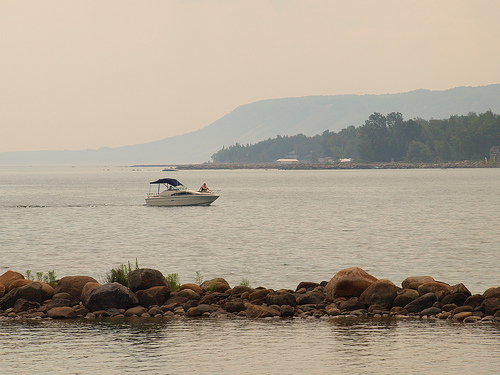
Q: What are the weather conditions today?
A: It is overcast.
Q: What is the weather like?
A: It is overcast.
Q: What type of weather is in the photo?
A: It is overcast.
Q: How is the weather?
A: It is overcast.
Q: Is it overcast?
A: Yes, it is overcast.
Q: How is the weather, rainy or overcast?
A: It is overcast.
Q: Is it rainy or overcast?
A: It is overcast.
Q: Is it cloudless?
A: No, it is overcast.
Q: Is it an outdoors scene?
A: Yes, it is outdoors.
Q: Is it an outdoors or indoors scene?
A: It is outdoors.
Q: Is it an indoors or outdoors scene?
A: It is outdoors.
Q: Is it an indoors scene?
A: No, it is outdoors.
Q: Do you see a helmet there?
A: No, there are no helmets.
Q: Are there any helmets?
A: No, there are no helmets.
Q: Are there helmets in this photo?
A: No, there are no helmets.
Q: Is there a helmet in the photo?
A: No, there are no helmets.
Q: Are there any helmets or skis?
A: No, there are no helmets or skis.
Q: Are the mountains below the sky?
A: Yes, the mountains are below the sky.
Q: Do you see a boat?
A: Yes, there is a boat.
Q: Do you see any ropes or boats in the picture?
A: Yes, there is a boat.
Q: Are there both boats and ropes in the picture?
A: No, there is a boat but no ropes.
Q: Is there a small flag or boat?
A: Yes, there is a small boat.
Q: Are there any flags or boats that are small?
A: Yes, the boat is small.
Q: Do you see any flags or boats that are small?
A: Yes, the boat is small.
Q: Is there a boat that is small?
A: Yes, there is a small boat.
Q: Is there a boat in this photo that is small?
A: Yes, there is a boat that is small.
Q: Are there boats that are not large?
A: Yes, there is a small boat.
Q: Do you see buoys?
A: No, there are no buoys.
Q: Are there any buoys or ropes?
A: No, there are no buoys or ropes.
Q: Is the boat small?
A: Yes, the boat is small.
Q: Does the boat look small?
A: Yes, the boat is small.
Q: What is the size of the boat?
A: The boat is small.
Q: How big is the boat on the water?
A: The boat is small.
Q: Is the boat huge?
A: No, the boat is small.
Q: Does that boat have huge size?
A: No, the boat is small.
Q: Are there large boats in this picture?
A: No, there is a boat but it is small.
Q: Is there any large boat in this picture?
A: No, there is a boat but it is small.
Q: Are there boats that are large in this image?
A: No, there is a boat but it is small.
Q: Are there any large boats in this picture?
A: No, there is a boat but it is small.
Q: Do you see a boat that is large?
A: No, there is a boat but it is small.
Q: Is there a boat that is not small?
A: No, there is a boat but it is small.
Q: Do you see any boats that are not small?
A: No, there is a boat but it is small.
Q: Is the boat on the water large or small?
A: The boat is small.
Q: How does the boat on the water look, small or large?
A: The boat is small.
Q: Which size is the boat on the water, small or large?
A: The boat is small.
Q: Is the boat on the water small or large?
A: The boat is small.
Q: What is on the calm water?
A: The boat is on the water.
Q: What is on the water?
A: The boat is on the water.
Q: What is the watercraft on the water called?
A: The watercraft is a boat.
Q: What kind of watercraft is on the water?
A: The watercraft is a boat.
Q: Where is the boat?
A: The boat is on the water.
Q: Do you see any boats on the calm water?
A: Yes, there is a boat on the water.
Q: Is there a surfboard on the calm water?
A: No, there is a boat on the water.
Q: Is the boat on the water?
A: Yes, the boat is on the water.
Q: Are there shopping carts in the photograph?
A: No, there are no shopping carts.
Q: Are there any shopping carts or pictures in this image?
A: No, there are no shopping carts or pictures.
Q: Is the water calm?
A: Yes, the water is calm.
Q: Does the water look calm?
A: Yes, the water is calm.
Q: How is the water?
A: The water is calm.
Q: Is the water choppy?
A: No, the water is calm.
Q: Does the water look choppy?
A: No, the water is calm.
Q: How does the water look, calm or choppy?
A: The water is calm.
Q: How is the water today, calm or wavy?
A: The water is calm.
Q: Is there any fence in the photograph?
A: No, there are no fences.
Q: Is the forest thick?
A: Yes, the forest is thick.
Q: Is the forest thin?
A: No, the forest is thick.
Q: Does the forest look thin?
A: No, the forest is thick.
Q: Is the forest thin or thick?
A: The forest is thick.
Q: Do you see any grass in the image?
A: Yes, there is grass.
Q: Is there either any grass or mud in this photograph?
A: Yes, there is grass.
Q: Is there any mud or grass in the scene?
A: Yes, there is grass.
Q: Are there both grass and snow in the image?
A: No, there is grass but no snow.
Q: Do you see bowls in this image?
A: No, there are no bowls.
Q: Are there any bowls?
A: No, there are no bowls.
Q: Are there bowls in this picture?
A: No, there are no bowls.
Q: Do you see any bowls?
A: No, there are no bowls.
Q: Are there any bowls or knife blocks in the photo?
A: No, there are no bowls or knife blocks.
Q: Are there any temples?
A: No, there are no temples.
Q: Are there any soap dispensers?
A: No, there are no soap dispensers.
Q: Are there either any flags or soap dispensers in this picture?
A: No, there are no soap dispensers or flags.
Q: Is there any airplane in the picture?
A: No, there are no airplanes.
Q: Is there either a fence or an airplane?
A: No, there are no airplanes or fences.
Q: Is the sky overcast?
A: Yes, the sky is overcast.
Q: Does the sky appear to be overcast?
A: Yes, the sky is overcast.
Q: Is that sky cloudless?
A: No, the sky is overcast.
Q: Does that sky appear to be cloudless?
A: No, the sky is overcast.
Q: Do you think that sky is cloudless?
A: No, the sky is overcast.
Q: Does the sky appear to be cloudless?
A: No, the sky is overcast.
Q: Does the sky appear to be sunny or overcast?
A: The sky is overcast.